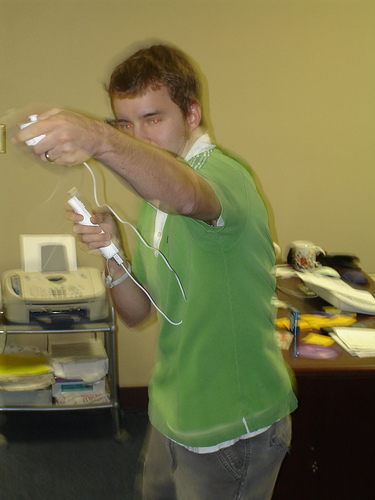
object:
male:
[17, 43, 299, 499]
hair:
[107, 44, 202, 121]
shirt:
[131, 132, 298, 454]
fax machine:
[4, 233, 111, 331]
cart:
[0, 289, 122, 446]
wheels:
[112, 431, 132, 457]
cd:
[294, 344, 338, 360]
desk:
[272, 258, 374, 500]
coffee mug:
[292, 238, 324, 272]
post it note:
[301, 332, 335, 348]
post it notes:
[284, 319, 311, 331]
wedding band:
[45, 150, 54, 163]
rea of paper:
[51, 340, 109, 385]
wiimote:
[67, 195, 120, 260]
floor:
[0, 409, 147, 499]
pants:
[140, 413, 293, 498]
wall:
[1, 1, 374, 389]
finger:
[41, 145, 63, 162]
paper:
[20, 235, 79, 273]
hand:
[71, 205, 121, 256]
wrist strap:
[106, 255, 132, 289]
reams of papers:
[0, 340, 108, 406]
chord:
[81, 161, 188, 327]